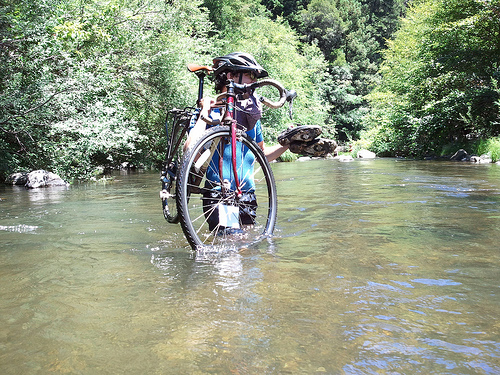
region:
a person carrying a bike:
[171, 55, 291, 254]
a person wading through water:
[177, 57, 306, 249]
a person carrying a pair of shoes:
[277, 121, 337, 157]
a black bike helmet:
[206, 50, 267, 80]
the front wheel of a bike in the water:
[176, 126, 277, 266]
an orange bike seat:
[185, 60, 210, 77]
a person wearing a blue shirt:
[210, 103, 258, 181]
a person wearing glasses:
[240, 70, 265, 83]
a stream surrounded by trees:
[2, 0, 497, 373]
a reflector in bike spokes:
[194, 146, 211, 177]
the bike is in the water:
[153, 42, 356, 293]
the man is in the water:
[83, 50, 350, 240]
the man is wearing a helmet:
[133, 50, 313, 133]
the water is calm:
[298, 205, 413, 337]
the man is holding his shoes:
[274, 109, 364, 177]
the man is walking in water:
[88, 38, 340, 290]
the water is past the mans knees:
[116, 63, 348, 291]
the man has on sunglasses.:
[213, 68, 300, 106]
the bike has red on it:
[174, 123, 358, 229]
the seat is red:
[186, 55, 237, 101]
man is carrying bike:
[150, 57, 300, 232]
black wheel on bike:
[155, 100, 290, 227]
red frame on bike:
[204, 87, 258, 181]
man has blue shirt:
[202, 103, 253, 177]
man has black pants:
[198, 174, 255, 239]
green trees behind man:
[2, 14, 447, 154]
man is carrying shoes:
[275, 120, 362, 184]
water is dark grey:
[347, 174, 482, 372]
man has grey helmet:
[212, 47, 256, 77]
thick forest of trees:
[2, 18, 426, 129]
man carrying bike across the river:
[120, 39, 300, 266]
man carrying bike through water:
[147, 23, 332, 274]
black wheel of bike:
[175, 129, 280, 262]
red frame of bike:
[224, 123, 239, 185]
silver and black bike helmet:
[210, 48, 258, 73]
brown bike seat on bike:
[180, 59, 205, 77]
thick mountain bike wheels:
[171, 139, 196, 219]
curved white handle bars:
[248, 69, 292, 113]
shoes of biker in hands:
[275, 112, 338, 164]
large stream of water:
[67, 160, 162, 322]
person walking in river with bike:
[185, 6, 390, 318]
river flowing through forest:
[89, 136, 499, 332]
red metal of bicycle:
[228, 99, 253, 193]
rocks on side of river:
[27, 165, 88, 205]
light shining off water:
[381, 249, 452, 362]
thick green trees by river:
[22, 17, 237, 140]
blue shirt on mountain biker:
[189, 88, 271, 189]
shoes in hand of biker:
[282, 108, 356, 178]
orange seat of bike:
[179, 61, 218, 70]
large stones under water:
[424, 230, 494, 320]